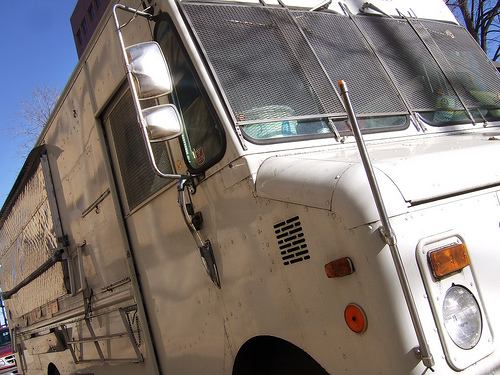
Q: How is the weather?
A: It is cloudless.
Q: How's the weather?
A: It is cloudless.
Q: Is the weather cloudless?
A: Yes, it is cloudless.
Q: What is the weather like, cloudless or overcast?
A: It is cloudless.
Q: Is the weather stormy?
A: No, it is cloudless.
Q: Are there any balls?
A: No, there are no balls.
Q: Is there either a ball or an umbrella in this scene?
A: No, there are no balls or umbrellas.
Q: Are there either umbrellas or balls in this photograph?
A: No, there are no balls or umbrellas.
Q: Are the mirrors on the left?
A: Yes, the mirrors are on the left of the image.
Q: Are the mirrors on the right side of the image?
A: No, the mirrors are on the left of the image.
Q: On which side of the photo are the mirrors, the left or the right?
A: The mirrors are on the left of the image.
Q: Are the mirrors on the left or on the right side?
A: The mirrors are on the left of the image.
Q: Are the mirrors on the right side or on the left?
A: The mirrors are on the left of the image.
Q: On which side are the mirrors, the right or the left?
A: The mirrors are on the left of the image.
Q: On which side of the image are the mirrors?
A: The mirrors are on the left of the image.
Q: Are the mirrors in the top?
A: Yes, the mirrors are in the top of the image.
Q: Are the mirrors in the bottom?
A: No, the mirrors are in the top of the image.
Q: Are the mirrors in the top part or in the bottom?
A: The mirrors are in the top of the image.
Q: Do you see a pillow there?
A: No, there are no pillows.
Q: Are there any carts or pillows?
A: No, there are no pillows or carts.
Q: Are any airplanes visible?
A: No, there are no airplanes.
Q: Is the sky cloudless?
A: Yes, the sky is cloudless.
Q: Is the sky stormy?
A: No, the sky is cloudless.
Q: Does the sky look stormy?
A: No, the sky is cloudless.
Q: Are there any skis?
A: No, there are no skis.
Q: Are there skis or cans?
A: No, there are no skis or cans.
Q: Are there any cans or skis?
A: No, there are no skis or cans.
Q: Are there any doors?
A: Yes, there is a door.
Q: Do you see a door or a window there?
A: Yes, there is a door.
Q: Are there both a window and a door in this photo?
A: Yes, there are both a door and a window.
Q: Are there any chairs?
A: No, there are no chairs.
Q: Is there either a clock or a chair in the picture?
A: No, there are no chairs or clocks.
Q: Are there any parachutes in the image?
A: No, there are no parachutes.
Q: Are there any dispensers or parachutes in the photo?
A: No, there are no parachutes or dispensers.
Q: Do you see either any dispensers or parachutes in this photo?
A: No, there are no parachutes or dispensers.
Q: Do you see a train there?
A: No, there are no trains.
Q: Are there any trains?
A: No, there are no trains.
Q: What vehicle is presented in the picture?
A: The vehicle is a van.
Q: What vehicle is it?
A: The vehicle is a van.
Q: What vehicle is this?
A: This is a van.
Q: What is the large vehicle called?
A: The vehicle is a van.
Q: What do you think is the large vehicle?
A: The vehicle is a van.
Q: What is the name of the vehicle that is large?
A: The vehicle is a van.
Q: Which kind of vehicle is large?
A: The vehicle is a van.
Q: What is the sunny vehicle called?
A: The vehicle is a van.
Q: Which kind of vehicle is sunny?
A: The vehicle is a van.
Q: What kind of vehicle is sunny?
A: The vehicle is a van.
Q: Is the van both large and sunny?
A: Yes, the van is large and sunny.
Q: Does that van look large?
A: Yes, the van is large.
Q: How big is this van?
A: The van is large.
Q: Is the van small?
A: No, the van is large.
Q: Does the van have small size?
A: No, the van is large.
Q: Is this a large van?
A: Yes, this is a large van.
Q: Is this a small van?
A: No, this is a large van.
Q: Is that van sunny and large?
A: Yes, the van is sunny and large.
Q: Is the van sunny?
A: Yes, the van is sunny.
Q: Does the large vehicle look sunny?
A: Yes, the van is sunny.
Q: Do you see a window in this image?
A: Yes, there is a window.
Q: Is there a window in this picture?
A: Yes, there is a window.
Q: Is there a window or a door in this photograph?
A: Yes, there is a window.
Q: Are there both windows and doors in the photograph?
A: Yes, there are both a window and a door.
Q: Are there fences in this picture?
A: No, there are no fences.